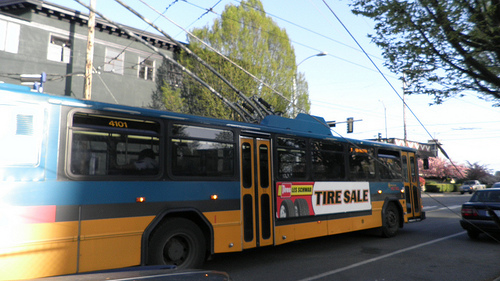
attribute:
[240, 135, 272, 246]
door — yellow, orange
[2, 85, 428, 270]
bus — blue, yellow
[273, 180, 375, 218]
sign — white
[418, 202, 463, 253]
line on road — white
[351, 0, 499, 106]
tree — green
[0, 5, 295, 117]
building — gray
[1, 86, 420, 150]
top of bus — blue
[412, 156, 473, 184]
trees — pink